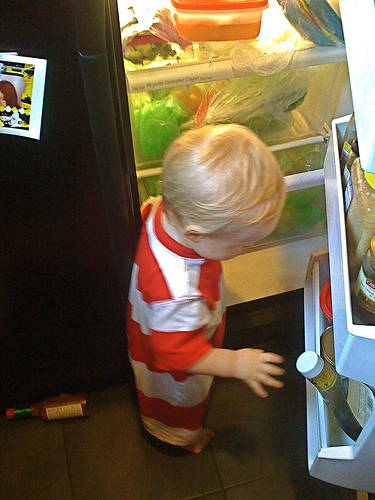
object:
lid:
[171, 0, 269, 17]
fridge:
[101, 0, 374, 495]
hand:
[233, 346, 286, 400]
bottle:
[4, 391, 87, 422]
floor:
[0, 340, 373, 499]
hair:
[157, 122, 287, 243]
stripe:
[132, 224, 173, 309]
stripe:
[145, 327, 211, 372]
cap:
[292, 348, 326, 383]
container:
[170, 0, 270, 43]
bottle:
[295, 349, 374, 442]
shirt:
[126, 194, 227, 446]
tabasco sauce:
[30, 391, 89, 419]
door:
[299, 0, 375, 496]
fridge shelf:
[321, 113, 374, 390]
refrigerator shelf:
[303, 248, 375, 495]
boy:
[124, 123, 288, 455]